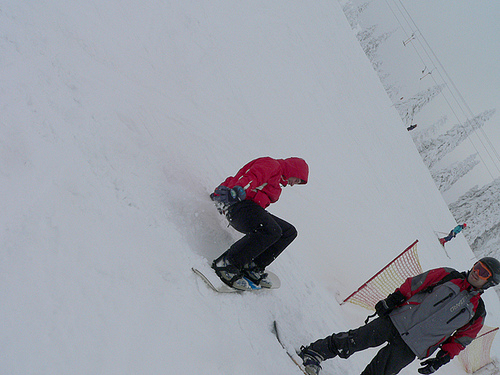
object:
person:
[209, 155, 312, 292]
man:
[296, 254, 499, 373]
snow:
[2, 2, 498, 375]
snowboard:
[189, 260, 284, 298]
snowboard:
[270, 318, 308, 373]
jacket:
[224, 155, 311, 209]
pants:
[224, 197, 300, 274]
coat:
[387, 266, 487, 361]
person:
[440, 223, 470, 250]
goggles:
[472, 260, 491, 283]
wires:
[352, 3, 500, 184]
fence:
[336, 238, 500, 374]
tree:
[414, 100, 498, 171]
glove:
[209, 184, 248, 208]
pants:
[308, 309, 415, 375]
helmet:
[476, 256, 499, 288]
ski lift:
[398, 28, 420, 52]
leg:
[214, 199, 285, 292]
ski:
[430, 226, 457, 259]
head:
[277, 148, 311, 190]